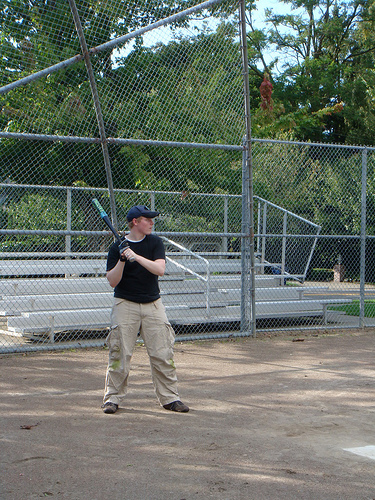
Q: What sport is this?
A: Baseball.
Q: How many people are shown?
A: One.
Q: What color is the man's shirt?
A: Black.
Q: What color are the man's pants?
A: Tan.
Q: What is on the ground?
A: Dirt.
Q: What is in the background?
A: A fence.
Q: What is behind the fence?
A: Trees.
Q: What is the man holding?
A: A bat.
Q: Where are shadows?
A: On the ground.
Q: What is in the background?
A: Trees.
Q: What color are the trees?
A: Green.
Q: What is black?
A: Boy's shirt.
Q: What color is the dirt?
A: Brown.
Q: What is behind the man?
A: A fence.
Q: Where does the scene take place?
A: On a baseball field.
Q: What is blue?
A: Sky.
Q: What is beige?
A: Boy's pants.